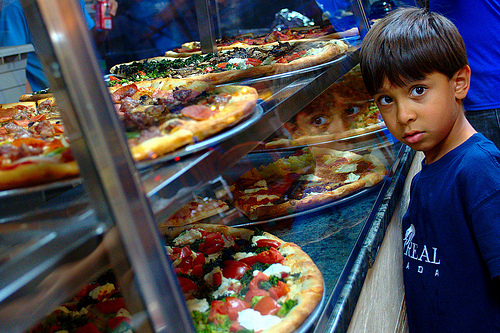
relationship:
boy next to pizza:
[348, 12, 499, 332] [231, 150, 385, 210]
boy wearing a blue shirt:
[348, 12, 499, 332] [400, 150, 499, 332]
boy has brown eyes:
[348, 12, 499, 332] [380, 85, 431, 107]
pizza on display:
[231, 150, 385, 210] [13, 2, 383, 321]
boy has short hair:
[348, 12, 499, 332] [355, 3, 472, 87]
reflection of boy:
[271, 48, 379, 174] [348, 12, 499, 332]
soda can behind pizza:
[95, 1, 116, 31] [231, 150, 385, 210]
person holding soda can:
[16, 1, 115, 89] [95, 1, 116, 31]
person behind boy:
[423, 3, 499, 143] [348, 12, 499, 332]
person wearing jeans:
[423, 3, 499, 143] [467, 109, 499, 135]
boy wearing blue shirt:
[348, 12, 499, 332] [400, 150, 499, 332]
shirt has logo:
[400, 150, 499, 332] [396, 223, 445, 281]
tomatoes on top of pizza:
[217, 258, 272, 311] [40, 229, 328, 332]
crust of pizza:
[362, 153, 385, 191] [231, 150, 385, 210]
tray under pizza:
[191, 150, 386, 228] [231, 150, 385, 210]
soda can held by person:
[95, 1, 116, 31] [16, 1, 115, 89]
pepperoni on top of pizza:
[180, 99, 219, 127] [7, 80, 254, 192]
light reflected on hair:
[390, 12, 471, 40] [355, 3, 472, 87]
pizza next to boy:
[231, 150, 385, 210] [348, 12, 499, 332]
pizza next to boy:
[40, 229, 328, 332] [348, 12, 499, 332]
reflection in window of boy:
[271, 48, 379, 174] [348, 12, 499, 332]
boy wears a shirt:
[348, 12, 499, 332] [400, 150, 499, 332]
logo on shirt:
[396, 223, 445, 281] [400, 150, 499, 332]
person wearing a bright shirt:
[423, 3, 499, 143] [426, 0, 498, 105]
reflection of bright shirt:
[317, 1, 375, 50] [426, 0, 498, 105]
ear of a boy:
[450, 65, 481, 111] [348, 12, 499, 332]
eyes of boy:
[380, 85, 431, 107] [348, 12, 499, 332]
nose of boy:
[394, 102, 418, 127] [348, 12, 499, 332]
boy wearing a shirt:
[348, 12, 499, 332] [400, 150, 499, 332]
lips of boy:
[401, 132, 430, 142] [348, 12, 499, 332]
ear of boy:
[450, 65, 481, 111] [348, 12, 499, 332]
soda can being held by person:
[95, 1, 116, 31] [16, 1, 115, 89]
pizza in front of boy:
[231, 150, 385, 210] [348, 12, 499, 332]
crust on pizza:
[362, 153, 385, 191] [231, 150, 385, 210]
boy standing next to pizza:
[348, 12, 499, 332] [231, 150, 385, 210]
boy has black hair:
[348, 12, 499, 332] [355, 3, 472, 87]